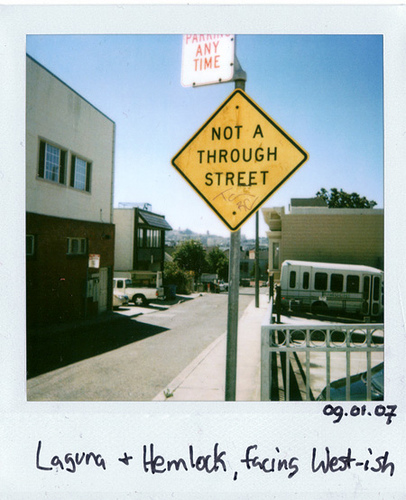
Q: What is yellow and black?
A: The sign.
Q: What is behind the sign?
A: A bus.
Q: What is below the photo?
A: Writing.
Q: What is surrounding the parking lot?
A: Metal fence.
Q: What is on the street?
A: Gray pavement.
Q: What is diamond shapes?
A: The sign.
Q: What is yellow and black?
A: The sign.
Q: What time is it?
A: Afternoon.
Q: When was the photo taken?
A: During the daytime.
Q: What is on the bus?
A: Windows.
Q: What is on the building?
A: Windows.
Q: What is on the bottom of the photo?
A: Words.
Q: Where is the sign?
A: On a pole.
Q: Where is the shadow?
A: On the street.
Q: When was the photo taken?
A: Daytime.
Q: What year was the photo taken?
A: 2007.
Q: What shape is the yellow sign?
A: Diamond.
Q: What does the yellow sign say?
A: Not a through street.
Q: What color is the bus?
A: White.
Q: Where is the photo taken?
A: Laguna and Hemlock.